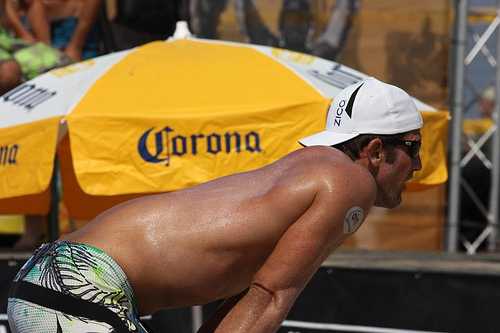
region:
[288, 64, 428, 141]
He has a white hat.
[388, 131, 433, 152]
He is wearing black sun glasses.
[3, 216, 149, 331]
He is wearing white trunks.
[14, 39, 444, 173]
The umbrella is white and yellow.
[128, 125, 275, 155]
The lettering is blue.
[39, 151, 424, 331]
He is not wearing a shirt.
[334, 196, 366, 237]
He has a sticker on his arm.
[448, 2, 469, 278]
The pole is grey.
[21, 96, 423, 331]
He is kneeling.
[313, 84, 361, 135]
The lettering is black.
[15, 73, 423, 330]
a man leaning forward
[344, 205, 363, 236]
sticker on a man's shirt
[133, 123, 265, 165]
the corona logo in blue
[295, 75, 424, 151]
a man's white hat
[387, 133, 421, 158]
a man's black glasses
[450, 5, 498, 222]
thin metal support beams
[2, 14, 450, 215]
top of a yellow and white umbrella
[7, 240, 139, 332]
a man's board shorts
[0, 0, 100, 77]
two people sitting in the distance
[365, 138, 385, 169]
the ear of a man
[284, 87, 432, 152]
A white cap on the man head.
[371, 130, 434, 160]
The man is wearing sunglasses.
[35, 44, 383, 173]
A yellow umbrella with word "Corona" written on it.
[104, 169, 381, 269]
The man is not wearing a shirt.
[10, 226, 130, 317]
The man is wearing swim trunks.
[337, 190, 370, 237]
The man has a sticker on his arm.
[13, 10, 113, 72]
People sitting at table.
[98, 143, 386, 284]
The man is wet.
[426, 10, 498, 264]
A iron gate on the walkway.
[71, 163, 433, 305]
The man is bending over.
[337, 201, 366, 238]
Tempory tattoo of a sports sponser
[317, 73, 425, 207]
Young man wearing sunglasses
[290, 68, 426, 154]
White ZICO baseball cap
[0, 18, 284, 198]
Part of a Corona beach umbrella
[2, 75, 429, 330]
Physically fit and tan young man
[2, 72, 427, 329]
Toned and athletic young man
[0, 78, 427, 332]
Shirtless young man wearing a tempory tattoo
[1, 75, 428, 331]
Shirtless young man wearing swimming trunks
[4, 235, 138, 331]
Top half of multi-color swimming trunks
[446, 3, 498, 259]
Some silver tone stage scaffolding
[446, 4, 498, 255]
Steel latticed support beam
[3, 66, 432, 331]
Male beach volleyball player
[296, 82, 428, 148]
Baseball cap worn backwards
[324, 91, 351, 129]
Zico sponsored baseball cap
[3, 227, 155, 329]
Player's multicolored athletic shorts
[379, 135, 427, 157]
Black dark sun glasses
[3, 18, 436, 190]
Yellow and white umbrella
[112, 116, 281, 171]
Corona sponsored sports umbrella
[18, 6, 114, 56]
Blue clad volleyball spectator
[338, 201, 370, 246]
Volleyball players arm patch